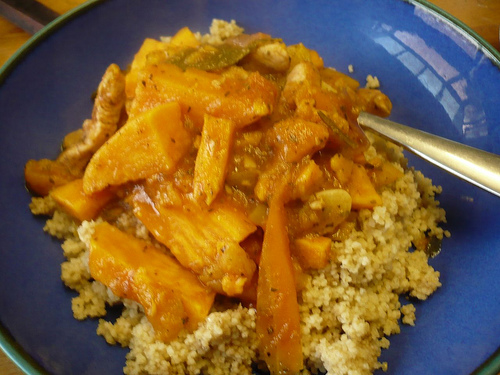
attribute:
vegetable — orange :
[55, 55, 412, 282]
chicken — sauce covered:
[73, 59, 304, 304]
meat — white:
[143, 156, 298, 298]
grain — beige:
[327, 228, 440, 373]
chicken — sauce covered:
[190, 111, 237, 206]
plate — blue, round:
[5, 2, 495, 372]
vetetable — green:
[168, 42, 248, 67]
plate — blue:
[22, 22, 484, 372]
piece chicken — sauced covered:
[152, 68, 251, 185]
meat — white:
[84, 56, 371, 367]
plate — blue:
[18, 10, 498, 270]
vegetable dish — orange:
[23, 26, 392, 373]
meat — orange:
[34, 19, 383, 374]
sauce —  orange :
[229, 141, 278, 178]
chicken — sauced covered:
[40, 179, 110, 221]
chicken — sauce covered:
[76, 99, 190, 196]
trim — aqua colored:
[393, 4, 497, 74]